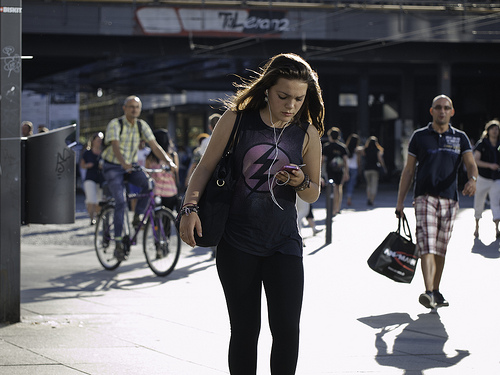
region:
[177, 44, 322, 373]
long haired brunette listening to music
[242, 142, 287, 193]
black lightening in a pink circle logo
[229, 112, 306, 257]
black and pink tank top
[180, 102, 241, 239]
over sized black handbag with straps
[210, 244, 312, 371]
black legging pants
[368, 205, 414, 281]
red white and black plastic shopping bag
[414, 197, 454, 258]
red and white plaid shorts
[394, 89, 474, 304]
bald man walking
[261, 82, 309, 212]
white corded earbuds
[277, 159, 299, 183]
pink shiny small smartphone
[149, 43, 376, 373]
lady walking on side walk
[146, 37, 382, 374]
lady with earphones in her ears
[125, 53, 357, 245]
lady holding pink phone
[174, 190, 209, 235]
lady wearing bracelets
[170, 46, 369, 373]
lady wearing black leggings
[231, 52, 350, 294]
lady wearing top with lightning picture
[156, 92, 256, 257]
lady holding black bag over shoulder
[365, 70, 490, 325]
man wearing shorts walking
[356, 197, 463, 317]
man holding black, white and red bag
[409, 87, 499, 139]
man wearing glasses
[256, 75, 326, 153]
Lady has on earplugs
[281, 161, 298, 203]
Phone is purple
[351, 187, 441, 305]
Man holding bag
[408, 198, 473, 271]
Pants has stripes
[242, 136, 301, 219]
The shirt has a lighting print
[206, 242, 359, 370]
Pants are black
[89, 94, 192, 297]
Man on bicycle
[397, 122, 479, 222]
The shirt is blue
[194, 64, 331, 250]
Woman is carrying a purse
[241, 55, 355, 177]
Lady is looking down at her phone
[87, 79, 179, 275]
Man on bicycle.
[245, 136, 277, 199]
Lightening bolt on girl's tank top.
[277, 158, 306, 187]
Girl's hand holding cellphone.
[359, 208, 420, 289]
Black bag being held by man in plaid shorts.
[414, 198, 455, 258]
Plaid shorts worn by man in black shirt.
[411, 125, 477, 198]
Black shirt worn by man wearing plaid pants.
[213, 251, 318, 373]
Black stretch pants worn by girl.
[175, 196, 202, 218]
Bracelets on worn by girl.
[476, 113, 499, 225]
Lady wearing white capri pants.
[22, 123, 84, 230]
Small black garbage bin hanging on side wall.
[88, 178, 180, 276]
a purple bike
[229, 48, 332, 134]
a girls hair blowing i the wind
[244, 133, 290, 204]
a black lightning bolt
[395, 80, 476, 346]
a man walking down the sidewalk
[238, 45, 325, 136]
a young lady listening to music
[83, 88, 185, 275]
an elderly man riding bike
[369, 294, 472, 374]
a shadow of a man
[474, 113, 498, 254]
a lady wearing capris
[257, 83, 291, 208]
a pair of white headphoes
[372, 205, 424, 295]
a black bag